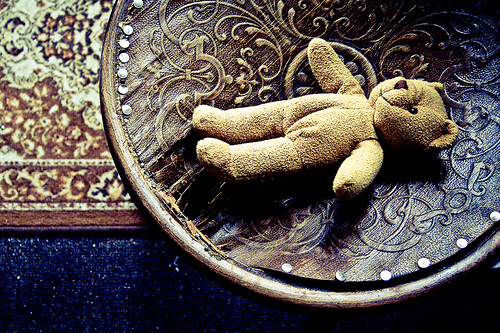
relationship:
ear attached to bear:
[426, 117, 459, 151] [190, 36, 458, 198]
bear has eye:
[190, 36, 458, 198] [403, 101, 422, 115]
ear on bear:
[415, 78, 445, 93] [190, 36, 458, 198]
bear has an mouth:
[190, 36, 458, 198] [376, 82, 396, 106]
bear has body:
[190, 36, 458, 198] [189, 38, 379, 192]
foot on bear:
[193, 136, 237, 182] [196, 138, 240, 168]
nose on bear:
[393, 80, 407, 90] [190, 36, 458, 198]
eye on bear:
[404, 104, 421, 114] [190, 36, 458, 198]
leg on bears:
[195, 131, 301, 181] [188, 133, 277, 173]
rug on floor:
[31, 21, 81, 153] [47, 159, 380, 312]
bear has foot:
[183, 26, 419, 205] [176, 128, 288, 192]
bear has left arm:
[190, 36, 458, 198] [330, 138, 383, 201]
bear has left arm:
[190, 36, 458, 198] [326, 143, 393, 203]